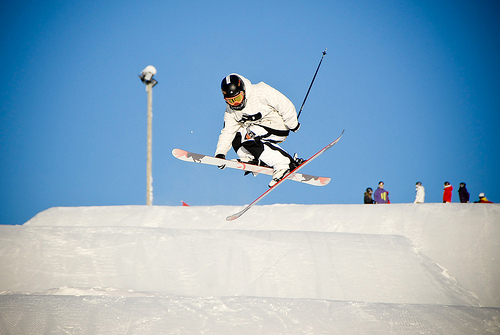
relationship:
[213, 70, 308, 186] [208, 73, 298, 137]
skier wearing a jacket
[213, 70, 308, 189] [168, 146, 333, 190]
skier holding skis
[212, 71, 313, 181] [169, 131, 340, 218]
person on skis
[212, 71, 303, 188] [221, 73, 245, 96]
person wearing helmet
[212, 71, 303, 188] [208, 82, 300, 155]
person wearing jacket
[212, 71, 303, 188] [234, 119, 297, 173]
person wearing pants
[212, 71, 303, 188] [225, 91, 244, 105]
person wearing ski googles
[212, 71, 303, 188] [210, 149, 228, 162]
person wearing glove